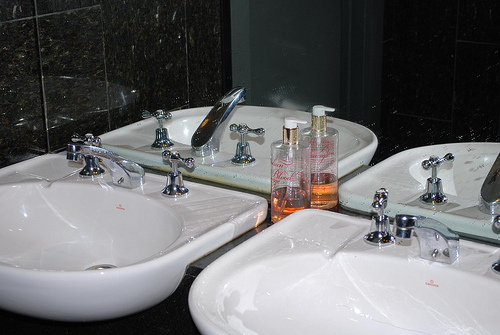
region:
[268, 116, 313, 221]
nearly empty hand soap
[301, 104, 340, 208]
reflection of bottle of hand soap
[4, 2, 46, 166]
black wall tile with gold flecks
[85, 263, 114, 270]
part of silver sink drain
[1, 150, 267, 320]
white porcelien sink on the left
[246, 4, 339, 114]
reflection of closed door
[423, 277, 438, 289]
red letters on the sink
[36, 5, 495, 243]
large mirror behind sinks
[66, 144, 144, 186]
silver faucet for the left sink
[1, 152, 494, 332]
black counter top surrounding the sinks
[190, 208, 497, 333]
White porcelain sink.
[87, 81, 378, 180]
Reflection of sink in mirror.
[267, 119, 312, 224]
Hand soap in clear bottle.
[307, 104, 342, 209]
Reflection of hand soap in mirror.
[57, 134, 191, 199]
Silver faucet and handles of sink.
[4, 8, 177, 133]
Dark brown tile on wall.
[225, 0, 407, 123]
White door reflection in mirror.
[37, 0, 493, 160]
Mirror behind bathroom sinks.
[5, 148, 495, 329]
Two white bathroom sinks.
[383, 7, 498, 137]
Reflection of dark tile in mirror.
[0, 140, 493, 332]
The sinks are white.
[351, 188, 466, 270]
The faucet is silver.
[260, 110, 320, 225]
The soap is on the counter.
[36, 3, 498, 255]
The mirror has reflections.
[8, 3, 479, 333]
The light is shining on the sink.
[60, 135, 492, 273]
The faucets are off.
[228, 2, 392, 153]
The reflection of the door.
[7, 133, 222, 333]
The sink is circular.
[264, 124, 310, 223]
The soap is almost empty.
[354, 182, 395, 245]
The faucet is silver.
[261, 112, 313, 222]
a soap dispenser.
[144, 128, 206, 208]
a sink faucet knob.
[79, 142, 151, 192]
a chrome sink faucet.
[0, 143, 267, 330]
A large white bathroom sink.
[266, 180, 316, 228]
soap at the bottom of a container.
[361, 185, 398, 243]
a sink faucet control knob.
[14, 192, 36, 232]
light reflecting on a sink.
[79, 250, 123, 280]
a sink drain in a sink.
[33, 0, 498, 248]
a large bathroom mirror.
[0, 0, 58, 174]
a marble bathroom wall.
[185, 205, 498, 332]
a white porcelain bathroom sink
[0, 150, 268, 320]
a white porcelain bathroom sink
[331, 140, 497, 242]
reflection of a white porcelain bathroom sink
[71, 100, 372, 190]
reflection of a white porcelain bathroom sink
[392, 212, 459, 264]
a chrome bathroom faucet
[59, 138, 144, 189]
a chrome bathroom faucet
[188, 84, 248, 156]
a chrome bathroom faucet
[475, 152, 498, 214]
a chrome bathroom faucet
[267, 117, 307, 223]
a bottle of soap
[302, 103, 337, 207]
reflection of a bottle of soap